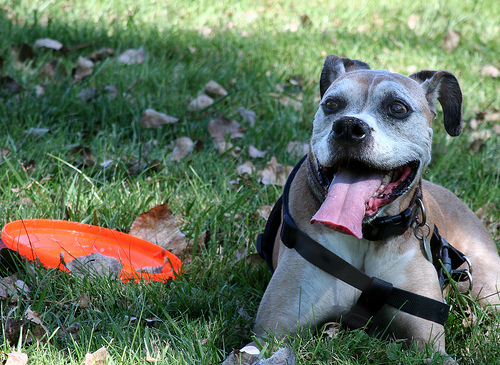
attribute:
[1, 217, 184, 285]
frisbee — orange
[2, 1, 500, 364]
grass — green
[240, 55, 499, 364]
dog — laying, gray, white, black, sitting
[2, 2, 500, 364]
photo — taken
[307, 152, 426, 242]
collar — dog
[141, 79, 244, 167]
leaves — brown